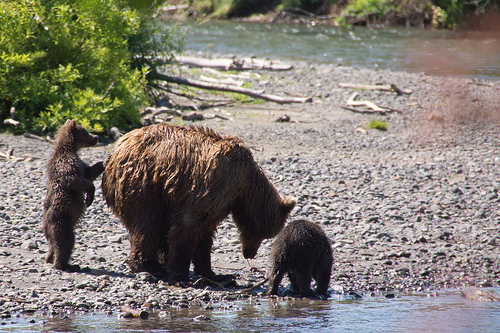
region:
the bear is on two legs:
[36, 116, 97, 251]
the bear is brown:
[105, 111, 275, 277]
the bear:
[110, 126, 270, 278]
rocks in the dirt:
[364, 177, 457, 251]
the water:
[363, 310, 422, 330]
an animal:
[271, 224, 337, 305]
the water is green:
[318, 22, 380, 59]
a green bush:
[6, 5, 124, 108]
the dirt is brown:
[296, 100, 329, 126]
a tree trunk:
[162, 73, 281, 104]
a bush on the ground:
[6, 13, 133, 120]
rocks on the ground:
[338, 147, 475, 281]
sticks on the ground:
[197, 56, 370, 125]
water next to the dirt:
[221, 17, 488, 63]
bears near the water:
[33, 115, 350, 279]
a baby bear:
[40, 113, 100, 260]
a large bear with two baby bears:
[43, 107, 358, 284]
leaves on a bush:
[20, 10, 143, 120]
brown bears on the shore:
[11, 109, 324, 304]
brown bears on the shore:
[29, 108, 325, 302]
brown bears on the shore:
[45, 110, 330, 303]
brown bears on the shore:
[47, 113, 325, 303]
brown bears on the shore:
[40, 118, 330, 302]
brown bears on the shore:
[32, 113, 343, 311]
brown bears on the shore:
[48, 120, 323, 306]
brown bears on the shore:
[33, 112, 323, 313]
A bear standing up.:
[41, 116, 108, 273]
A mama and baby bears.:
[38, 117, 333, 299]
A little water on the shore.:
[0, 286, 499, 331]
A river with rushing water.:
[140, 18, 498, 80]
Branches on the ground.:
[338, 78, 415, 118]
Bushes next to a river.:
[1, 0, 498, 143]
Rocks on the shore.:
[0, 48, 497, 332]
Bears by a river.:
[39, 115, 334, 298]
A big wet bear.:
[99, 122, 297, 288]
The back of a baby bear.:
[233, 220, 333, 299]